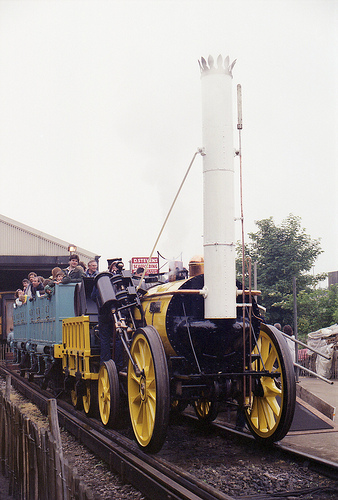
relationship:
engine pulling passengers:
[40, 51, 306, 456] [10, 247, 114, 315]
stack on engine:
[193, 51, 245, 322] [40, 51, 306, 456]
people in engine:
[13, 247, 145, 311] [40, 51, 306, 456]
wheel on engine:
[124, 321, 175, 451] [40, 51, 306, 456]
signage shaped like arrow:
[131, 256, 162, 277] [131, 252, 171, 269]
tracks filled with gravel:
[1, 368, 335, 494] [37, 401, 336, 496]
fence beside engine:
[1, 375, 72, 496] [40, 51, 306, 456]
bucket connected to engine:
[12, 277, 81, 345] [40, 51, 306, 456]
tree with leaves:
[239, 210, 318, 307] [238, 214, 319, 293]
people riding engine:
[13, 247, 145, 311] [40, 51, 306, 456]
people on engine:
[13, 247, 145, 311] [40, 51, 306, 456]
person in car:
[85, 258, 100, 274] [3, 245, 144, 372]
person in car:
[65, 255, 83, 269] [3, 245, 144, 372]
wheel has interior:
[124, 321, 175, 451] [129, 335, 156, 438]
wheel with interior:
[124, 321, 175, 451] [129, 335, 156, 438]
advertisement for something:
[131, 256, 162, 277] [134, 258, 158, 272]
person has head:
[85, 258, 100, 274] [84, 258, 102, 271]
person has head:
[65, 255, 83, 269] [67, 254, 82, 270]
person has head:
[31, 273, 46, 283] [29, 275, 42, 287]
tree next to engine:
[239, 210, 318, 307] [40, 51, 306, 456]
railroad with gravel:
[1, 368, 335, 494] [37, 401, 336, 496]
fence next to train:
[1, 375, 72, 496] [8, 42, 304, 452]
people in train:
[13, 247, 145, 311] [8, 42, 304, 452]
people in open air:
[13, 247, 145, 311] [5, 0, 330, 311]